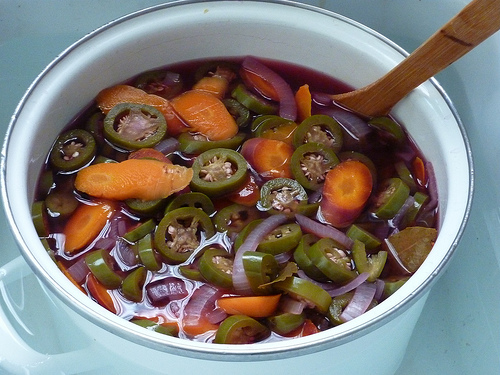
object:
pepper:
[191, 148, 252, 197]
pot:
[0, 0, 481, 362]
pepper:
[103, 103, 168, 146]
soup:
[74, 68, 395, 301]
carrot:
[62, 202, 111, 250]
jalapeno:
[287, 103, 344, 182]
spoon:
[324, 0, 500, 119]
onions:
[297, 211, 354, 250]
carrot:
[318, 162, 378, 229]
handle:
[0, 255, 85, 357]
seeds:
[307, 154, 325, 161]